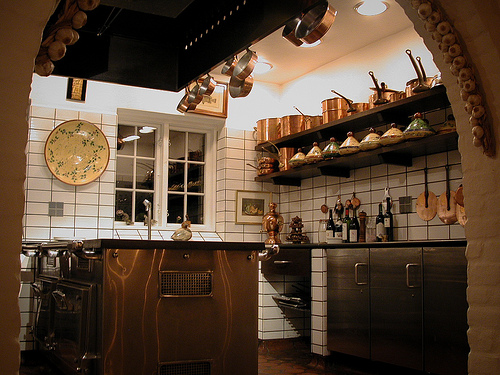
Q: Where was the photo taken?
A: In a kitchen.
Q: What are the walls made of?
A: Tile.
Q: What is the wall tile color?
A: White.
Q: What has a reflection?
A: Window.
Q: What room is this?
A: Kitchen.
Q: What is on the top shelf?
A: Pots.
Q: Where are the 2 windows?
A: In the kitchen.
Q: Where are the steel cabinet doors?
A: On the bottom right.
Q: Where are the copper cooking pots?
A: On top shelf.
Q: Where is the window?
A: On the wall.